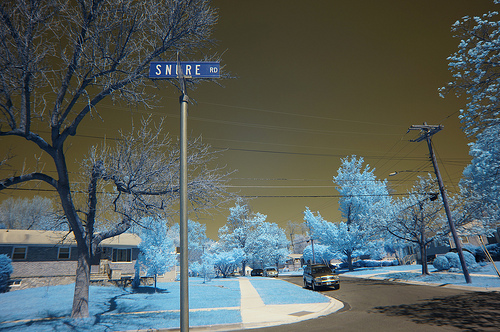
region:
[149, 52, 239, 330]
Street sign and pole.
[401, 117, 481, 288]
Utility pole for the delivery of electricity.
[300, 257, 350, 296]
SUV traversing down a clean road.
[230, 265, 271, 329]
Sidewalk semi plowed for pedestrian transportation.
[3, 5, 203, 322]
Bare winter foliage.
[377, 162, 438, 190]
Street light to illuminate the road.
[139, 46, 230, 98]
Street sign to identify location.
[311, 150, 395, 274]
Trees with snow remnants on the leaves.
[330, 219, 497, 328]
Uncontrolled road intersection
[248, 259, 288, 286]
Cars parked along the roadway.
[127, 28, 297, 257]
a street sign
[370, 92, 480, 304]
a tall power pole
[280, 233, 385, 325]
a vehicle on the street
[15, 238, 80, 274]
two windows on a building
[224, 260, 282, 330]
a side walk next to the road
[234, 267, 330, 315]
patch of grass in between the side walk and street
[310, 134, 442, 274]
a tall tree in the distance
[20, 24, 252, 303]
a tree with no leaves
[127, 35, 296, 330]
a tall street sign on the corner of the road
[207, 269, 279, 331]
corner of two sidewalks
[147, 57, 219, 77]
A blue sign telling the name of the road.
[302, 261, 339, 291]
A SUV riding on the right of the road.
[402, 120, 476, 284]
A crooked electrical pole on the sidewalk.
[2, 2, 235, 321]
A very large tree with no leaves in it.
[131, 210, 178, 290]
A blue tree outside in the park.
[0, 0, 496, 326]
The most beautiful park in the world.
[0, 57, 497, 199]
Electrical wires on top of the street.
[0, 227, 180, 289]
A very nice building near the park.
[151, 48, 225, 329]
A pole with the sign Snare Road written on it.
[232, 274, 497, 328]
The entire length of the road.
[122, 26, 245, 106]
a street sign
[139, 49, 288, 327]
a street sign pole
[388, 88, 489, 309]
a tall power pole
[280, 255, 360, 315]
a vehicle on the road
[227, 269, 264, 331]
sidewalk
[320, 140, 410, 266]
tall trees in the distance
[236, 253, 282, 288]
two vehicles on the road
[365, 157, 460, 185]
street light on pole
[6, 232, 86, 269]
windows on a building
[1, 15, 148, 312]
a tree next to the sidewalk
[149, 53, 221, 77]
A street sign blue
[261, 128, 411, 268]
A tall blue tree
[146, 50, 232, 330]
A pole with a sign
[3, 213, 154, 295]
A building with windows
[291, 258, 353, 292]
An SUV that is uncolored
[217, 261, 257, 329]
A public side walk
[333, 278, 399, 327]
The road for cars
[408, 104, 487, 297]
A utility electrical pole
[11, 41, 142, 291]
A dead tree with no leaves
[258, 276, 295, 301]
Grass pallet on median